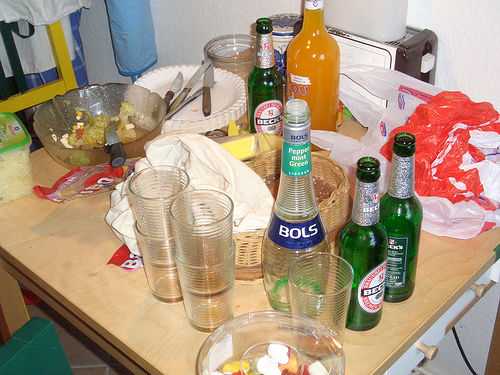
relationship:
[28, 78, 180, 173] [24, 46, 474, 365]
bowl sitting on table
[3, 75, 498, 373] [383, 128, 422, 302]
table filled with bottle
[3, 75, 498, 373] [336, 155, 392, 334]
table filled with bottle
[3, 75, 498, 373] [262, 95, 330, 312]
table filled with bottle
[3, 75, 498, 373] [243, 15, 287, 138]
table filled with bottle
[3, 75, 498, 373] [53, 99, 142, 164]
table filled with food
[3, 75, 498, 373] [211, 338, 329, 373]
table filled with food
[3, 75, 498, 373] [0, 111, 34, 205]
table filled with food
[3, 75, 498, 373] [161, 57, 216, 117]
table filled with dinner ware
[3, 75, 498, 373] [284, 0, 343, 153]
table filled with drink